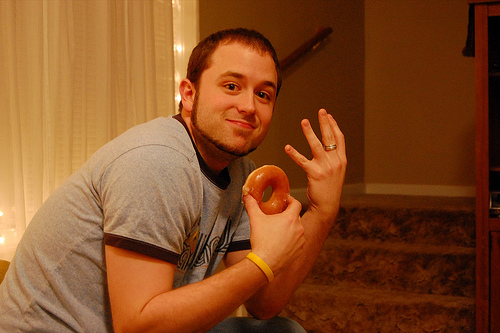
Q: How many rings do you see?
A: One.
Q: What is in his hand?
A: Doughnut.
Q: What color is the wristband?
A: Yellow.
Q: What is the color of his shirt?
A: Grey.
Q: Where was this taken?
A: In someone's home.